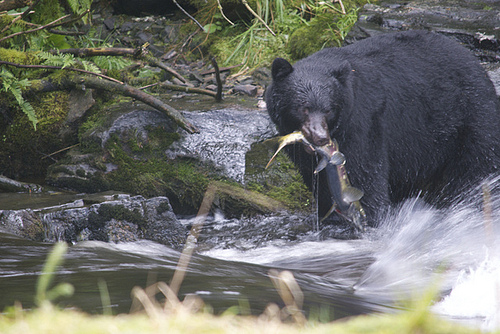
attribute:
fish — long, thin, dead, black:
[260, 128, 367, 233]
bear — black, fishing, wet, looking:
[263, 30, 497, 237]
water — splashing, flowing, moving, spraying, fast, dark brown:
[5, 185, 499, 334]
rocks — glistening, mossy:
[89, 85, 311, 244]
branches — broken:
[3, 5, 226, 118]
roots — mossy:
[7, 34, 186, 124]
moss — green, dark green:
[1, 42, 314, 232]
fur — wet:
[264, 26, 499, 227]